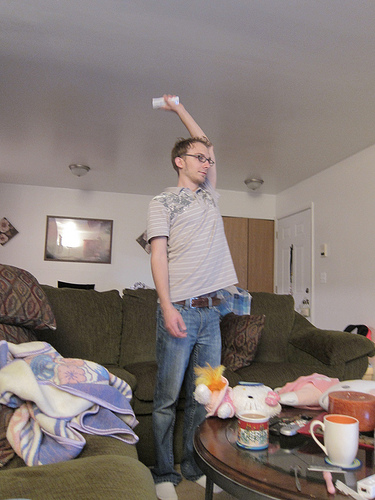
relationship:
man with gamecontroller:
[148, 129, 226, 401] [130, 91, 190, 110]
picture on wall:
[45, 217, 116, 266] [0, 171, 142, 280]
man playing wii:
[148, 129, 226, 401] [145, 89, 184, 108]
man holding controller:
[148, 129, 226, 401] [130, 91, 190, 110]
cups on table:
[305, 417, 365, 468] [192, 426, 280, 499]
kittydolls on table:
[199, 374, 291, 418] [192, 413, 375, 499]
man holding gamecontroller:
[148, 129, 226, 401] [130, 91, 190, 110]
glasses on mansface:
[194, 152, 214, 166] [195, 136, 211, 184]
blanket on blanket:
[3, 337, 137, 452] [0, 337, 140, 475]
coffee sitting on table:
[225, 411, 272, 454] [192, 426, 280, 499]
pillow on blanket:
[0, 260, 42, 324] [0, 337, 140, 475]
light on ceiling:
[67, 162, 94, 183] [10, 0, 360, 139]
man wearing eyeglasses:
[148, 129, 226, 401] [194, 152, 214, 166]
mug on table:
[305, 417, 365, 468] [192, 426, 280, 499]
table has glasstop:
[192, 426, 280, 499] [287, 445, 303, 461]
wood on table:
[189, 436, 273, 480] [192, 413, 375, 499]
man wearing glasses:
[148, 129, 226, 401] [194, 152, 214, 166]